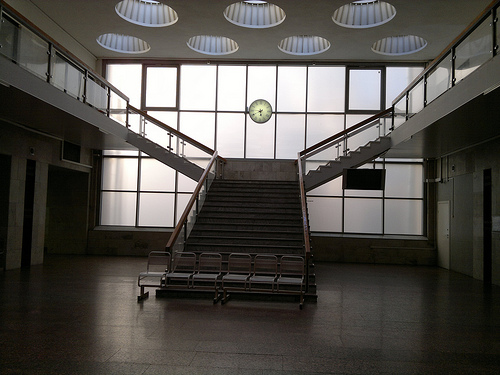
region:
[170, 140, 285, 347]
the stairs is blocked with chairs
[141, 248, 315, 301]
these are some seats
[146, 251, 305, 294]
the seats are metallic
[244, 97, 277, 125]
this is a clock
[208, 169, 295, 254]
this is a staircase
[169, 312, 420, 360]
this is the floor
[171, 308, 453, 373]
the floor is made of tiles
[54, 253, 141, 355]
the floor is shiny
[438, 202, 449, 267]
this is a door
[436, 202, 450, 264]
the door is wooden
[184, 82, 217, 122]
the wall is made of glass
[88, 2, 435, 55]
circular ceiling lights in the building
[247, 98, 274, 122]
a clock on the window wall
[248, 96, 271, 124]
the face of the clock is white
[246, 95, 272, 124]
the hands and numbers are black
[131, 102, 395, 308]
a central staircase in the lobby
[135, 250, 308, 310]
a bench of chairs at the foot of the stairs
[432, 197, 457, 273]
a closed white door in the lobby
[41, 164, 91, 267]
a hallway off the lobby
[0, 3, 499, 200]
the mezzanine has lucite rails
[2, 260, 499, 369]
the floor is shiny and clean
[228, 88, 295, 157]
clock hanging on window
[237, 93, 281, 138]
white clock face with black numbers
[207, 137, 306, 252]
stairs leading up to different level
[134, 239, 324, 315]
chairs in front of stairs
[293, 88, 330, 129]
window behind the clock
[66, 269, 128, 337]
floor with light bouncing off of it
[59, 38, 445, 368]
empty room in the daytime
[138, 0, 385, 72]
lights on the ceiling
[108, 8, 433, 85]
seven lights not turned on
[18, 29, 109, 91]
second level of building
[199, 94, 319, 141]
the clock is on the center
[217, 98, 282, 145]
the clock is on the center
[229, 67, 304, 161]
the clock is on the center